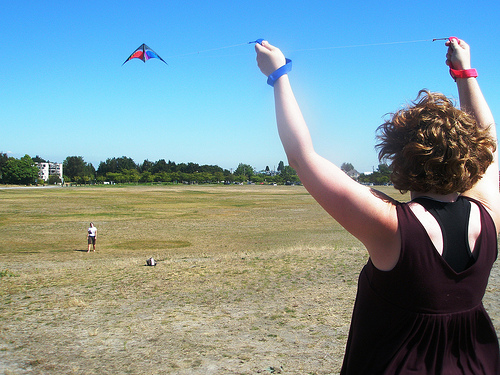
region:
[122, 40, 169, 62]
a colorful kite in the air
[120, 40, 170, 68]
blue and red triangular kite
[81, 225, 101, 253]
a person standing on the sand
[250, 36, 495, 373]
woman with her arms in the air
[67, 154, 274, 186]
line of trees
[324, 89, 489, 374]
woman wearing a black tanktop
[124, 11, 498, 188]
woman flying a kite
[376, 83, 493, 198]
short brown curly hair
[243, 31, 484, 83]
blue and red straps to the kite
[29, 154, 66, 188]
white building in the distance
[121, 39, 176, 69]
a blue and red kite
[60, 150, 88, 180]
a tall green tree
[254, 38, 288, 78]
the hand of a woman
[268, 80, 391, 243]
the arm of a woman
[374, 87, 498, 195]
a woman's brown hair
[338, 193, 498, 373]
a woman's black tank top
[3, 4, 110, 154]
part of a blue sky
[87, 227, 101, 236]
a man's white shirt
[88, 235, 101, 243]
a man's black shorts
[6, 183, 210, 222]
green and brown grass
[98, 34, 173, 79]
Kite in the sky.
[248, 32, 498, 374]
Girl is flying the kite.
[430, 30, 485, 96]
Red rope on right wrist.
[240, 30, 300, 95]
Blue rope on left wrist.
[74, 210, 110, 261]
Person looking at the kite.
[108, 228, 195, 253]
Grass circle on the ground.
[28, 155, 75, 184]
Building in the background.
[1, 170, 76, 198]
Road in front of the building.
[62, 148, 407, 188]
Trees in the background.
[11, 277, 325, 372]
The grass is dry.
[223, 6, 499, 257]
woman's hands in air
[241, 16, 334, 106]
blue handle around wrist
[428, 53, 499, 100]
red handle around wrist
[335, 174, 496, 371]
woman's shirt is brown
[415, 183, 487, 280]
black tank top under shirt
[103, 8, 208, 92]
kite is in the air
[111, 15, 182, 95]
kite is red and blue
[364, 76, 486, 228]
girl's hair is curly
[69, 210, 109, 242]
person wearing a white shirt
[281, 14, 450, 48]
string leads to kite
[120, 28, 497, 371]
a woman flying a kite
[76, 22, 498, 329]
flying a kite in a park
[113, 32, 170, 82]
a red and blue kite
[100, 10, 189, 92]
a kite in the air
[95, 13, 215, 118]
a red and blue kite in the sky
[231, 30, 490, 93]
red and blue kite wrist straps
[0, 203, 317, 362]
a person standing on a field of dry grass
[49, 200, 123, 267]
a person looking up at a kite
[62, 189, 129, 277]
a person looking towards the sky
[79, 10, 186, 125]
a red and blue kite hovering in the park